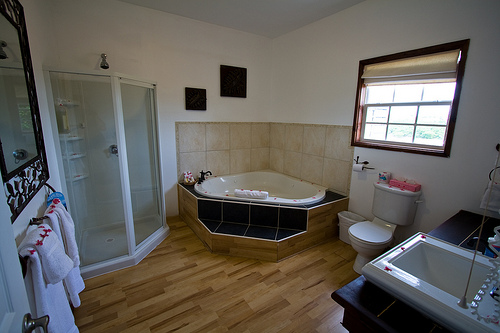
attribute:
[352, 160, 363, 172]
paper — white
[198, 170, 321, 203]
bathtub — large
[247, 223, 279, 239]
tile — black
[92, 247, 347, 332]
floor — wooden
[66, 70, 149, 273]
glass — enclosed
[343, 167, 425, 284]
toilet — white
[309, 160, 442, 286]
toilet — white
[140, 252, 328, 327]
wood floor — wooden, light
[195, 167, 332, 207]
tub — cornered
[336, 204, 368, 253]
waste bucket — white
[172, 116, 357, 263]
bathtub — triangle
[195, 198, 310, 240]
tile — blue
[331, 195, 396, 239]
toilet — white, porcelain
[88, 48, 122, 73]
shower head — silver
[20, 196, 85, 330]
towels — white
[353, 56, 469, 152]
mirror — black, metal 